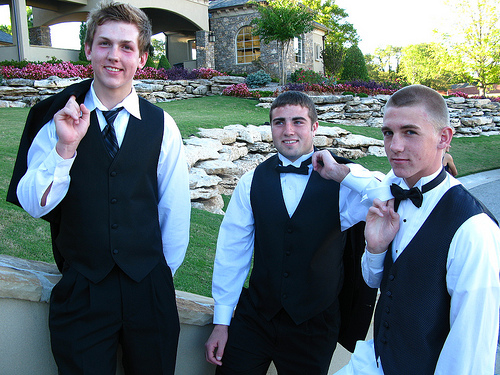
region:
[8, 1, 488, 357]
Three young boys dressed up for a special event.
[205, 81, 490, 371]
Two young boys wearing a black vest.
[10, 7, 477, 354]
All three boys carrying their jacket on the shoulder.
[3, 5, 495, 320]
Background with a nice landscape.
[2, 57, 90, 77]
Pink flowers in the garden.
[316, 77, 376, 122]
More flowers on the piled stones platform.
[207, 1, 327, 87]
Small stone walled house.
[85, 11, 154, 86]
Young man smiling for the picture.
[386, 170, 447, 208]
Young man wearing a bow tie.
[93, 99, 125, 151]
Young man with a striped blue and black tie.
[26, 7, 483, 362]
three guys posing a for a photo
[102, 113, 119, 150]
a black stripe neck tie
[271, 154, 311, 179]
a black bow tie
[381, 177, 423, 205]
a black bow tie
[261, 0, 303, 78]
a skinny tree with a bushy top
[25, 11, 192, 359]
a man wearing a black vest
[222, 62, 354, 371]
a man wearing a black vest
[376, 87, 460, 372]
a man wearing a black vest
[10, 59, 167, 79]
a row of bright pink flowers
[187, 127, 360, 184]
a stone enclave behind the men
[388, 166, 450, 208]
Black bow tie on man's neck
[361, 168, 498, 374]
White shirt with black vest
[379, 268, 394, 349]
Black buttons on black vest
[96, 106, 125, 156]
Striped tie on man's neck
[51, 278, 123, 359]
Wrinkles on front of man's pants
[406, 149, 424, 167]
Pimples on man's face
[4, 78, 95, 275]
Black jacket in man's hand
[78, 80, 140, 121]
White shirt collar folded onto black vest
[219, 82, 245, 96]
Small bush with pink flowers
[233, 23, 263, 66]
Arched window on side of building